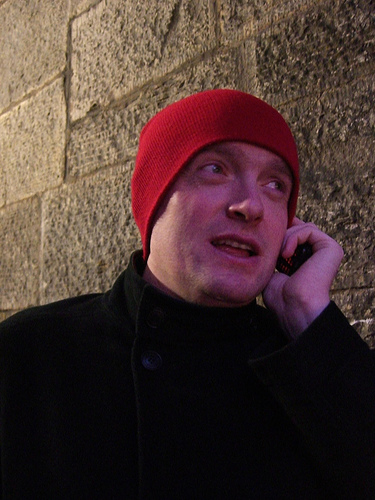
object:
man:
[0, 88, 374, 500]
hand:
[262, 212, 346, 343]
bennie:
[130, 87, 301, 262]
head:
[132, 84, 299, 309]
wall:
[0, 4, 373, 331]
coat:
[0, 251, 373, 497]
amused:
[191, 144, 286, 290]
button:
[140, 345, 168, 372]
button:
[140, 304, 171, 338]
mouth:
[202, 232, 264, 266]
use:
[270, 220, 311, 281]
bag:
[200, 171, 232, 185]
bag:
[266, 186, 285, 203]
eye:
[198, 164, 230, 179]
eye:
[264, 176, 289, 197]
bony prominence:
[277, 273, 316, 306]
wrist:
[270, 280, 333, 345]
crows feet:
[181, 164, 200, 186]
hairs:
[239, 151, 271, 174]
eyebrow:
[268, 156, 294, 181]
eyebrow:
[195, 142, 233, 162]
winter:
[2, 246, 364, 481]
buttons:
[281, 259, 291, 273]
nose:
[224, 169, 263, 223]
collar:
[107, 255, 271, 338]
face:
[167, 134, 294, 298]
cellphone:
[274, 234, 317, 275]